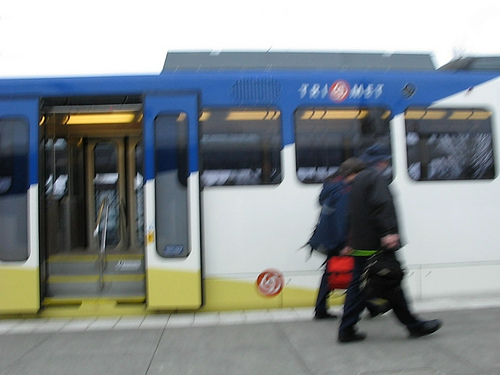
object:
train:
[1, 70, 500, 317]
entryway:
[44, 249, 148, 301]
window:
[179, 104, 284, 187]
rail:
[92, 198, 110, 283]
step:
[49, 275, 144, 298]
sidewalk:
[0, 302, 499, 375]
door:
[38, 97, 147, 314]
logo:
[253, 267, 287, 299]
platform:
[0, 293, 499, 374]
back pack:
[356, 245, 407, 305]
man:
[336, 144, 444, 341]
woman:
[306, 157, 391, 319]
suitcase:
[326, 255, 354, 287]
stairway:
[37, 292, 146, 304]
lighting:
[63, 111, 136, 129]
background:
[0, 0, 500, 374]